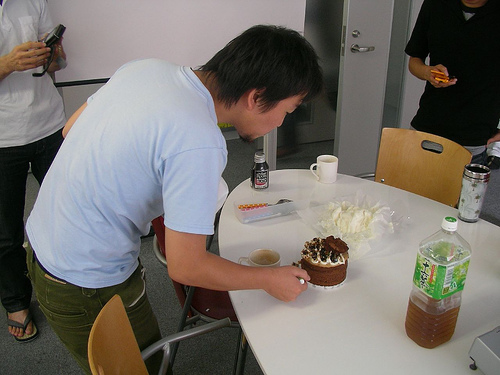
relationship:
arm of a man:
[160, 145, 305, 321] [27, 27, 312, 373]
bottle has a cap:
[408, 220, 463, 346] [442, 216, 458, 229]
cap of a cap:
[442, 216, 458, 229] [438, 212, 460, 232]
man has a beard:
[27, 27, 312, 373] [243, 131, 261, 144]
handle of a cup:
[304, 158, 318, 180] [306, 153, 337, 182]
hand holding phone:
[410, 56, 462, 96] [431, 61, 458, 86]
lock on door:
[348, 24, 365, 41] [328, 1, 400, 181]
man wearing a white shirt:
[61, 26, 320, 316] [37, 48, 213, 292]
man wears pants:
[27, 27, 312, 373] [72, 131, 135, 173]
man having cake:
[27, 27, 312, 373] [292, 235, 348, 286]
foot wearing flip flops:
[0, 295, 40, 349] [0, 299, 55, 345]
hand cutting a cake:
[281, 201, 355, 318] [291, 227, 354, 295]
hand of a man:
[395, 33, 464, 103] [392, 0, 483, 144]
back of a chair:
[369, 126, 484, 193] [356, 126, 475, 208]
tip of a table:
[236, 161, 358, 185] [212, 163, 482, 373]